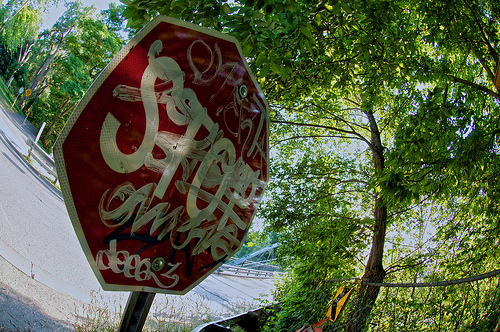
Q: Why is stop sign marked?
A: It's a bad neighborhood.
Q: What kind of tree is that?
A: It's a maple tree.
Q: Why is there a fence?
A: To protect pedestrians.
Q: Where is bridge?
A: It is over the river.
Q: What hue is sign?
A: Red.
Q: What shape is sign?
A: Octagon.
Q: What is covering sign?
A: Paint.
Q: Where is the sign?
A: On pole.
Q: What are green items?
A: Leaves.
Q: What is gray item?
A: Street.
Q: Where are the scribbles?
A: Sign post.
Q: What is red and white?
A: Signpost.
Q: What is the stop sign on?
A: A metal post.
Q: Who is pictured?
A: No one.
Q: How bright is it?
A: Fairly.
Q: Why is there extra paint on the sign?
A: Graffiti.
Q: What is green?
A: Trees.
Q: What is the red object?
A: Stop sign.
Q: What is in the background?
A: The street.